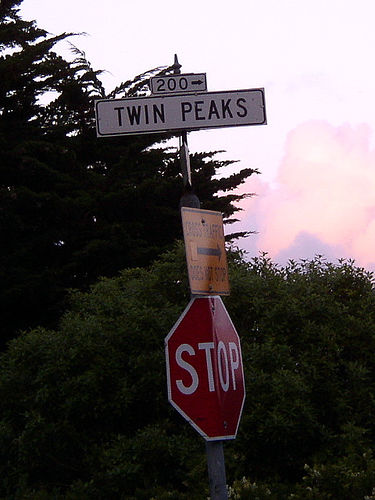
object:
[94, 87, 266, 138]
longer sign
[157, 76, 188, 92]
200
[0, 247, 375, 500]
bush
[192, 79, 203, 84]
arrow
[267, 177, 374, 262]
light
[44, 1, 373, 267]
daytime sky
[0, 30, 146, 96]
branches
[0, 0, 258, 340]
pine tree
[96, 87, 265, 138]
sign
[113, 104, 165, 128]
word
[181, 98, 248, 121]
word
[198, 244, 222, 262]
arrow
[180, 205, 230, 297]
sign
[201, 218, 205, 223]
bolt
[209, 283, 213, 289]
bolt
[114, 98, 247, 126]
letter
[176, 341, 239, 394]
writing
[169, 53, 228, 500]
pole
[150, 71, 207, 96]
sign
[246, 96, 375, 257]
clouds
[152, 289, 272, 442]
sign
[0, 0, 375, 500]
night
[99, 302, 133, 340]
leaves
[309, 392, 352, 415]
leaves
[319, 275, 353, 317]
leaves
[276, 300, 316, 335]
leaves